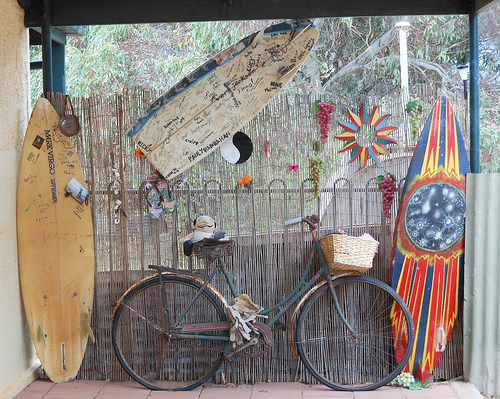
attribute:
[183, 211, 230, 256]
doll — man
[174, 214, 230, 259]
doll — stuffed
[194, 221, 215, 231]
mustache — black handlebar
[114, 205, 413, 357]
bike — blue, metal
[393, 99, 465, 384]
board — boggy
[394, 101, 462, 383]
stripes — flame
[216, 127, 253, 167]
yin yang — black and white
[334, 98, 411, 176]
plaque — blue, red, yellow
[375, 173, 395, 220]
grapes — artificial, purple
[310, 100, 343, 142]
grape — red, plastic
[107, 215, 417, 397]
bicycle — blue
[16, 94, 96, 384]
board — brown, boggy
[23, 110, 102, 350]
surfboard — wooden, brown, vertical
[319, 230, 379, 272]
basket — brown, wicker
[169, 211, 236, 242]
toy — stuffed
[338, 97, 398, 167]
sun pattern — blue red and yellow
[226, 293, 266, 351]
gloves — large, tan, cloth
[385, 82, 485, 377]
surfboard — red, blue, yellow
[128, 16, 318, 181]
surfboard — white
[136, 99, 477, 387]
fence — straw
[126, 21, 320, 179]
surf board — tan, blue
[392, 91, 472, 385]
surfboard — blue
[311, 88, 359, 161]
grapes — bunch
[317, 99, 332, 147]
grapes — red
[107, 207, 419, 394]
bike — old, rusty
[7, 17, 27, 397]
wall — yellow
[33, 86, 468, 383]
fence panel — brown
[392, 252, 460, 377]
stripes — red, yellow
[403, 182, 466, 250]
circle — grey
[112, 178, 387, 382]
pipes — metal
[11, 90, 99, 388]
surf board — wood, tan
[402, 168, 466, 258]
pattern — circular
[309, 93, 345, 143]
grapes — red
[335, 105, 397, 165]
points — yellow, blue, red